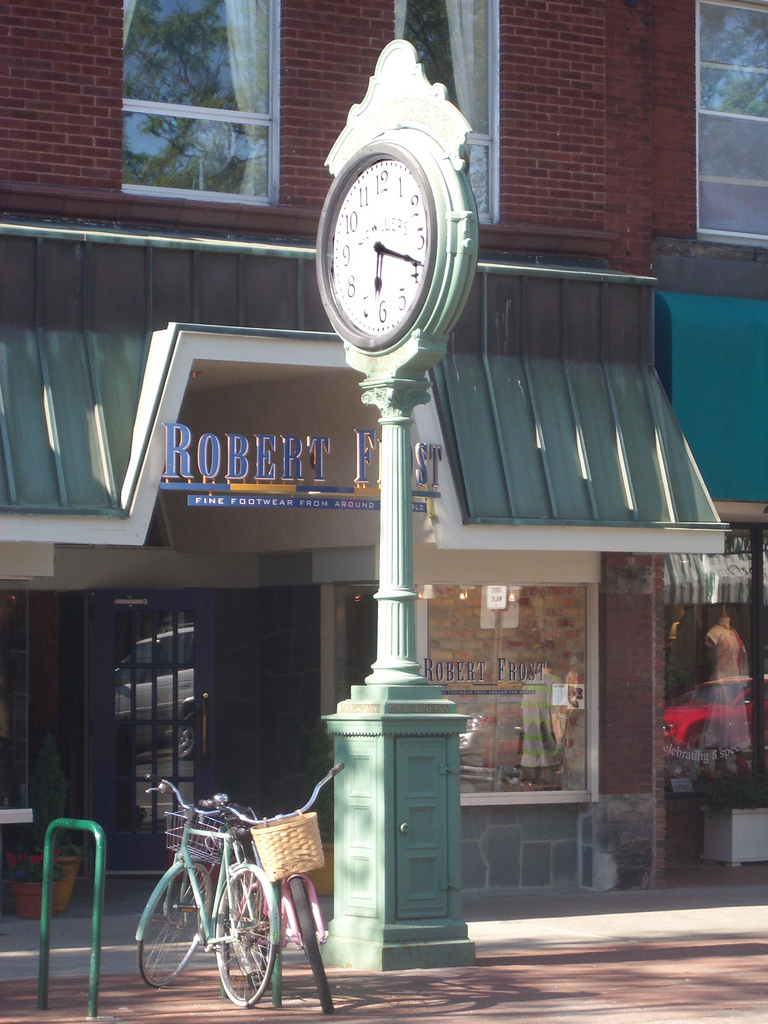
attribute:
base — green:
[352, 677, 512, 953]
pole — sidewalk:
[369, 424, 429, 672]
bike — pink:
[217, 761, 348, 1012]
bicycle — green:
[110, 759, 288, 993]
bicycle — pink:
[199, 758, 334, 1013]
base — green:
[332, 670, 467, 977]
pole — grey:
[316, 372, 477, 972]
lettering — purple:
[413, 642, 559, 702]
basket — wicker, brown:
[246, 811, 328, 883]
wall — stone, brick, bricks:
[5, 2, 694, 268]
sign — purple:
[164, 417, 443, 513]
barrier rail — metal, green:
[32, 815, 108, 1021]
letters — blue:
[164, 423, 443, 483]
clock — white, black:
[313, 142, 440, 348]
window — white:
[118, 1, 286, 207]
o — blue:
[196, 430, 222, 480]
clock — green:
[265, 21, 524, 994]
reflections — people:
[382, 553, 608, 811]